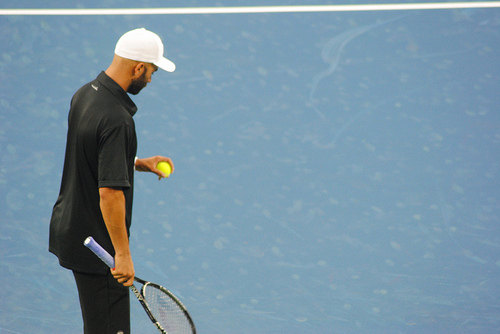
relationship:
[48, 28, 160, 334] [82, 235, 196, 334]
man holding racket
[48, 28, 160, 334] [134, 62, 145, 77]
man has ear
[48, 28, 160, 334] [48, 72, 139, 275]
man wearing shirt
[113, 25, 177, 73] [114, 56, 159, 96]
hat on top of head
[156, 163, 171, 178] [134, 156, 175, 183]
ball in hand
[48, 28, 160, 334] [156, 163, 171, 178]
man holding ball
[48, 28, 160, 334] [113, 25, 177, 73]
man wearing hat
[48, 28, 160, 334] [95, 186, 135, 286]
man has arm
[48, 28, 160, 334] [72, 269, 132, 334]
man wearing tennis shorts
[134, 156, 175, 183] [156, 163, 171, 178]
hand holding ball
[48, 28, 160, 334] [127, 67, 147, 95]
man has beard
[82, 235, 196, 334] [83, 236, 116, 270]
racket has handle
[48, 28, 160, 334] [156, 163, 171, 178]
man preparing to serve ball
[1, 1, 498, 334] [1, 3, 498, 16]
background has line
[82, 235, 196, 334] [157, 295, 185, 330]
racket has corporate logo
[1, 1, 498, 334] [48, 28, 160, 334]
ground under man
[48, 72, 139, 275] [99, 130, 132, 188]
shirt has sleeve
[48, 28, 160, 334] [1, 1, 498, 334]
man looking at background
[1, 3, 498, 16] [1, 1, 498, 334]
line on background